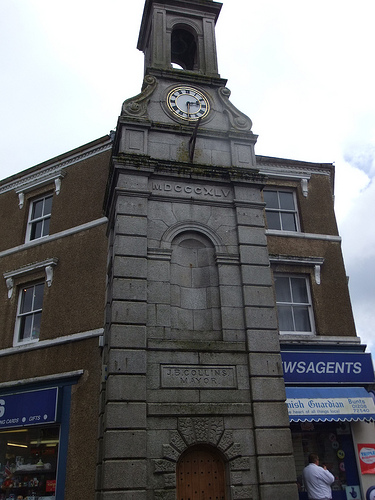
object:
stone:
[160, 364, 239, 389]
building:
[0, 3, 372, 498]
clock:
[163, 83, 212, 125]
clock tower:
[116, 2, 259, 157]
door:
[175, 442, 235, 498]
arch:
[166, 220, 222, 266]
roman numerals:
[193, 91, 198, 96]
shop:
[280, 347, 374, 500]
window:
[273, 266, 317, 337]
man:
[301, 454, 335, 499]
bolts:
[213, 473, 218, 480]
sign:
[0, 384, 62, 431]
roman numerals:
[203, 186, 214, 197]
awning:
[278, 386, 374, 424]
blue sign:
[284, 348, 374, 385]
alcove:
[162, 226, 227, 346]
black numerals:
[185, 89, 191, 94]